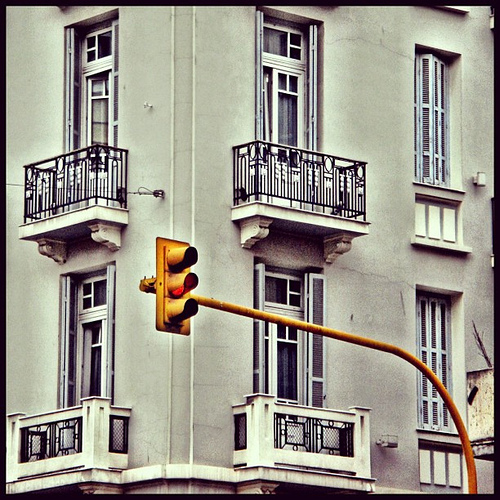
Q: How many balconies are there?
A: 4.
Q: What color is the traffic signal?
A: Red.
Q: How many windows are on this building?
A: 6.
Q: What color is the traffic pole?
A: Yellow.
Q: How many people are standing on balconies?
A: None.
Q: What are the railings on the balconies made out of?
A: Metal.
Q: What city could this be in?
A: Paris France.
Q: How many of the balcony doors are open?
A: None.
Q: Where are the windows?
A: On the building.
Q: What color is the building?
A: Brown.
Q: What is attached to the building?
A: Wire.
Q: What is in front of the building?
A: Light.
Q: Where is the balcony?
A: Under the windows.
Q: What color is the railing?
A: Black.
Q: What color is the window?
A: Gray.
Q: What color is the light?
A: Red.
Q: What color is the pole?
A: Yellow.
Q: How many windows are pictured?
A: Six.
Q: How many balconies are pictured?
A: Four.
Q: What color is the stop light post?
A: Yellow.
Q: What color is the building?
A: Grey.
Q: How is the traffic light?
A: Yellow.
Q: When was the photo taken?
A: Daytime.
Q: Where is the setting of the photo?
A: Exterior street.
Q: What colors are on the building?
A: Grey, black, white.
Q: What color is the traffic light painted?
A: Yellow.